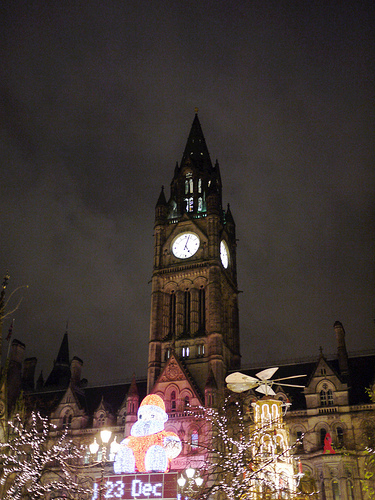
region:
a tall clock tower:
[145, 105, 241, 370]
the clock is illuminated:
[172, 231, 198, 257]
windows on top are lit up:
[183, 174, 204, 212]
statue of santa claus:
[114, 392, 182, 471]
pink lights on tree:
[180, 398, 304, 499]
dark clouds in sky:
[3, 1, 374, 387]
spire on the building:
[49, 321, 72, 384]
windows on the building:
[319, 387, 332, 405]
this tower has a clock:
[106, 104, 298, 385]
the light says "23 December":
[84, 464, 184, 498]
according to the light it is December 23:
[83, 467, 208, 498]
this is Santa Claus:
[78, 377, 192, 480]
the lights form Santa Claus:
[95, 367, 213, 481]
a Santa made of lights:
[95, 381, 200, 482]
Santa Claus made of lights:
[88, 383, 230, 493]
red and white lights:
[84, 375, 209, 488]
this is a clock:
[166, 215, 227, 283]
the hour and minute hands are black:
[140, 211, 226, 259]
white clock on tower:
[164, 227, 196, 274]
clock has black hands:
[173, 238, 205, 267]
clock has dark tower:
[152, 123, 217, 233]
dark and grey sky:
[262, 54, 348, 225]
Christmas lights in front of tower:
[128, 394, 179, 463]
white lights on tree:
[166, 403, 277, 495]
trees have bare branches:
[185, 387, 301, 496]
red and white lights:
[111, 391, 161, 469]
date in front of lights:
[87, 468, 167, 498]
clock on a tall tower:
[167, 229, 204, 259]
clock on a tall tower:
[215, 236, 233, 270]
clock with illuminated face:
[170, 228, 198, 260]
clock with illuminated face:
[217, 238, 230, 270]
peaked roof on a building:
[45, 316, 77, 393]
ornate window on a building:
[318, 384, 336, 407]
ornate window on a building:
[169, 386, 181, 417]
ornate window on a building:
[58, 409, 75, 429]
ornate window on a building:
[334, 425, 345, 448]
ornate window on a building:
[318, 426, 328, 449]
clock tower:
[128, 104, 267, 381]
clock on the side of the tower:
[167, 228, 206, 266]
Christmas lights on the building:
[0, 353, 341, 498]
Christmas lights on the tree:
[1, 403, 110, 497]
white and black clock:
[170, 230, 206, 264]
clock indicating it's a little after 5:
[166, 227, 209, 261]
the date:
[94, 474, 169, 499]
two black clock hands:
[180, 232, 195, 257]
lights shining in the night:
[248, 397, 304, 497]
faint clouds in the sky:
[0, 0, 373, 396]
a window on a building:
[159, 285, 174, 336]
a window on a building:
[181, 288, 187, 338]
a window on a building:
[198, 288, 206, 337]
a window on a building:
[317, 386, 325, 409]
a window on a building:
[328, 393, 333, 408]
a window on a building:
[320, 424, 330, 455]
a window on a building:
[327, 477, 343, 499]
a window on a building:
[322, 474, 326, 499]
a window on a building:
[58, 413, 67, 426]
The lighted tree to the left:
[2, 398, 102, 496]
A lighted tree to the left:
[3, 400, 93, 493]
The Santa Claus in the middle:
[81, 385, 191, 470]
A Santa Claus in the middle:
[95, 382, 190, 465]